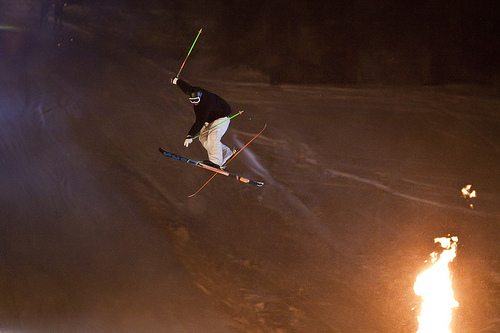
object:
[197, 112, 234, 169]
pants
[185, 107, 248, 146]
ski pole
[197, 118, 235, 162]
leg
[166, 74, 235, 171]
man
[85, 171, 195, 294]
tracks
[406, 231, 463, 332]
flame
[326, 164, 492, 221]
tracks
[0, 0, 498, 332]
snow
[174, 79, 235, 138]
shirt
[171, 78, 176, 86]
glove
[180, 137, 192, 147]
glove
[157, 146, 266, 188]
ski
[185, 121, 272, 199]
ski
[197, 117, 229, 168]
leg